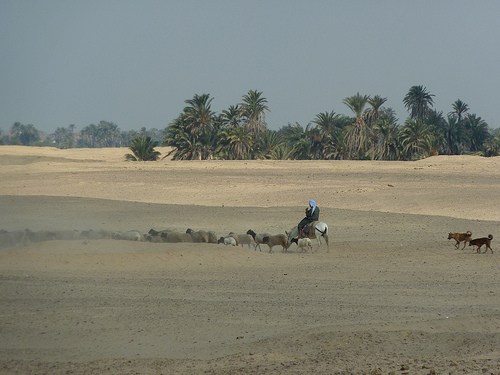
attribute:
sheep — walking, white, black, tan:
[124, 226, 291, 251]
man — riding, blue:
[301, 199, 326, 224]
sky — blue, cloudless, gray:
[6, 6, 495, 88]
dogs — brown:
[448, 229, 496, 256]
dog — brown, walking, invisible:
[448, 231, 472, 250]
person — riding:
[294, 200, 321, 232]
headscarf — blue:
[305, 199, 321, 217]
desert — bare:
[4, 5, 498, 375]